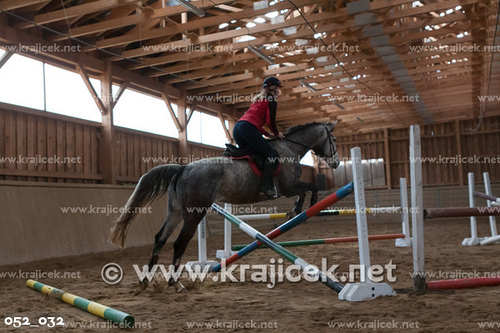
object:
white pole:
[349, 145, 374, 282]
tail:
[109, 163, 182, 247]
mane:
[286, 121, 333, 135]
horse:
[110, 120, 341, 293]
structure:
[185, 145, 399, 302]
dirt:
[0, 217, 499, 332]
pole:
[25, 277, 136, 328]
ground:
[0, 217, 499, 332]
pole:
[425, 276, 500, 290]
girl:
[232, 77, 283, 197]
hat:
[263, 77, 284, 89]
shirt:
[234, 93, 281, 136]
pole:
[224, 203, 232, 251]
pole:
[234, 206, 401, 220]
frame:
[231, 205, 404, 247]